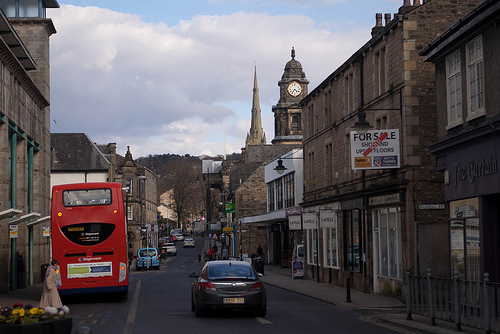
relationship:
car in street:
[133, 244, 162, 270] [60, 234, 415, 332]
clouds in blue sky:
[45, 3, 374, 155] [45, 0, 406, 157]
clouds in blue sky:
[45, 3, 374, 155] [120, 8, 207, 25]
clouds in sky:
[176, 16, 282, 81] [48, 0, 381, 157]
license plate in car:
[216, 289, 260, 310] [163, 234, 303, 324]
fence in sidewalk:
[403, 266, 498, 332] [253, 264, 498, 332]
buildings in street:
[2, 0, 496, 328] [28, 226, 413, 332]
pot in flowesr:
[14, 318, 73, 332] [6, 301, 73, 317]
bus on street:
[50, 181, 135, 301] [136, 233, 312, 332]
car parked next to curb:
[133, 247, 160, 270] [129, 254, 137, 274]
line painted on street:
[128, 273, 147, 327] [2, 215, 312, 332]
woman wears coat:
[33, 259, 72, 315] [44, 266, 64, 304]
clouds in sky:
[45, 3, 374, 155] [48, 0, 381, 157]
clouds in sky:
[45, 3, 374, 155] [38, 6, 385, 164]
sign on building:
[349, 128, 401, 171] [292, 12, 433, 300]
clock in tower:
[281, 75, 309, 120] [274, 45, 319, 141]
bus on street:
[49, 180, 131, 295] [133, 267, 188, 332]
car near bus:
[192, 260, 262, 302] [33, 159, 143, 304]